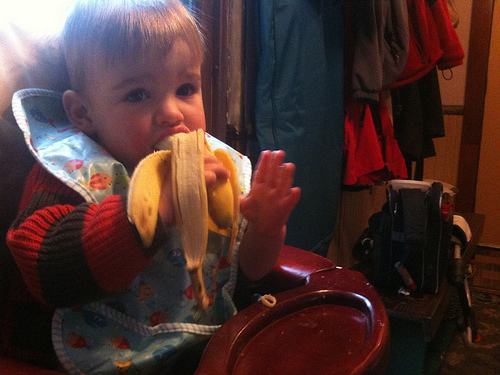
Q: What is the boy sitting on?
A: A highchair.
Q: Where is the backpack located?
A: On a bench.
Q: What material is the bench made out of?
A: Wood.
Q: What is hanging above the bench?
A: Coats.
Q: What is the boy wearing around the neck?
A: A bib.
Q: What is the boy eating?
A: A banana.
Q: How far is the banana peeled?
A: Halfway.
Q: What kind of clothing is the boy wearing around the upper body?
A: A sweater.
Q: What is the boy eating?
A: A banana.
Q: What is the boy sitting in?
A: A highchair.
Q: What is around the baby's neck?
A: A bib.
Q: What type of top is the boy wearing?
A: A sweater.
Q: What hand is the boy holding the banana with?
A: The right hand.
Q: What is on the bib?
A: Fish.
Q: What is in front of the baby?
A: A food tray.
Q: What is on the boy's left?
A: Hanging garments.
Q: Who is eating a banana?
A: The baby.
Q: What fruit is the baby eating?
A: Banana.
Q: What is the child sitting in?
A: High chair.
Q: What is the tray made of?
A: Wood.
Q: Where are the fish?
A: On the bib.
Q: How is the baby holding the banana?
A: With right hand.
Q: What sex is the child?
A: Male.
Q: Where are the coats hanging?
A: On the wall.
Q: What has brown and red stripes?
A: Sweater.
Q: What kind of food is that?
A: A banana.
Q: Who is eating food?
A: A baby.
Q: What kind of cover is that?
A: A cover for a baby.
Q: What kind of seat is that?
A: A seat for a baby.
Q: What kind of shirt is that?
A: A red and black shirt.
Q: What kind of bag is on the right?
A: A black backpack.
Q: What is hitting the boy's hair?
A: Sunlight.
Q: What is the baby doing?
A: Eating.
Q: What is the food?
A: Banana.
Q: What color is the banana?
A: Yellow.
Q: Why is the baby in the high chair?
A: For support.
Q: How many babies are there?
A: One.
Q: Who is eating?
A: A baby.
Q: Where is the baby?
A: In the highchair.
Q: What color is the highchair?
A: Red.